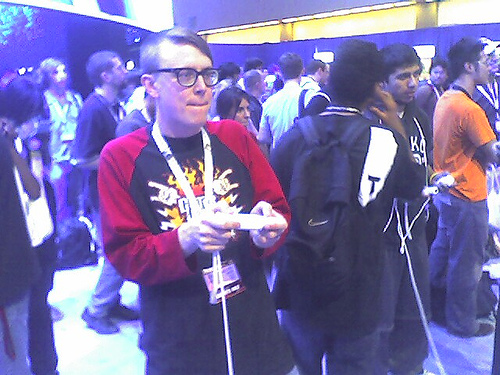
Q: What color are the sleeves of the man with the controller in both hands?
A: White.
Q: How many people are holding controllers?
A: 2.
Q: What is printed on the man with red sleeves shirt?
A: Guitar hero.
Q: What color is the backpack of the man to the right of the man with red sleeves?
A: Black.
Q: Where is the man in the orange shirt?
A: All the way to the right.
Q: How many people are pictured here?
A: 15.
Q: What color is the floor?
A: White.